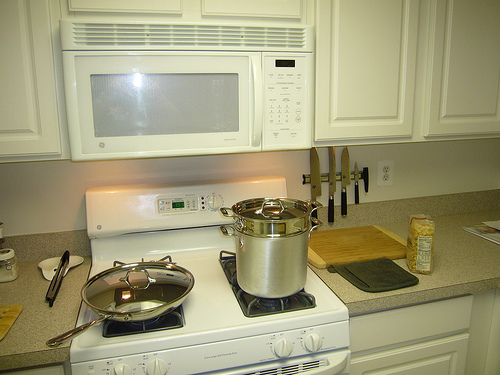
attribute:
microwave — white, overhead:
[59, 17, 315, 162]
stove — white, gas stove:
[69, 174, 351, 375]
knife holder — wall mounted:
[301, 166, 368, 193]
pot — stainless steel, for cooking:
[220, 197, 322, 237]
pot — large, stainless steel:
[219, 218, 323, 300]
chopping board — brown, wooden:
[308, 225, 409, 269]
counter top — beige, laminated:
[1, 208, 499, 371]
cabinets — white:
[0, 0, 499, 374]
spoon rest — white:
[38, 256, 84, 281]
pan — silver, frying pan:
[47, 262, 195, 347]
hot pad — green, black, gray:
[326, 258, 418, 293]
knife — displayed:
[309, 148, 321, 231]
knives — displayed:
[310, 148, 360, 231]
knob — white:
[304, 334, 322, 353]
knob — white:
[274, 338, 293, 361]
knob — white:
[145, 358, 168, 375]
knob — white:
[114, 363, 136, 375]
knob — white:
[208, 195, 223, 210]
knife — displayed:
[328, 148, 336, 222]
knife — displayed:
[340, 145, 350, 216]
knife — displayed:
[354, 161, 359, 203]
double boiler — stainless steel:
[220, 198, 322, 298]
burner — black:
[219, 250, 317, 318]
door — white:
[0, 0, 63, 159]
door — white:
[314, 1, 420, 142]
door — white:
[422, 0, 498, 139]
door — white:
[350, 333, 470, 375]